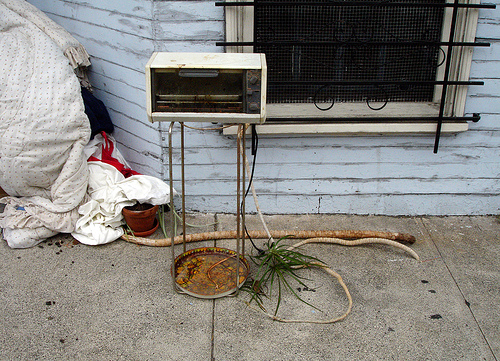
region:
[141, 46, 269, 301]
toaster oven sitting on a plant stand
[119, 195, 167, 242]
small pot for a plant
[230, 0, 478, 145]
window covered with black security bars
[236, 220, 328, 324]
house plant laying on a sidewalk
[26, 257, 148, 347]
sidewalk made of concrete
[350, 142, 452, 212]
light blue clapboard siding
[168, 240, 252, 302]
rusted area of a plant stand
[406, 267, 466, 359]
black stains on a sidewalk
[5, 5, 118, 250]
pile of clothing on a sidewalk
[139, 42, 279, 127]
white toaster oven outside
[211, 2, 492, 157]
Window has black wrought iron on it.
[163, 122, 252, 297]
Metal stand is sitting on sidewalk.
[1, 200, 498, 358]
Sidewalk is paved cement.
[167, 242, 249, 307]
A rusty tray is under the stand.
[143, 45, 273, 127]
A toaster oven is sitting on the stand.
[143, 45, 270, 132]
The toaster oven is white.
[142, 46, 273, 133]
Toaster oven shows signs of great use.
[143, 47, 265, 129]
The toaster oven appears quite dirty.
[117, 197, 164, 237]
Flower pot on ground beside stand.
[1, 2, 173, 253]
Pile of clothes lie against the house.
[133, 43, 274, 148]
the old toaster oven is white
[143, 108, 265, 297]
the stand is rusty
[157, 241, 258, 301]
the plate is rusty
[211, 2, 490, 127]
the window has iron bars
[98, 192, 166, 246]
the flower pot is red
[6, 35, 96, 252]
the big rag is polka dot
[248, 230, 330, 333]
the plant is green and out of place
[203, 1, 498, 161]
the window bars are black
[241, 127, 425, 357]
the cord is very long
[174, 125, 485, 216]
the house is blue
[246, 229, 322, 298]
a small green plant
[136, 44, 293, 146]
a broken toaster oven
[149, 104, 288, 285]
a small metal stand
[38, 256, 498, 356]
a grey cement sidewalk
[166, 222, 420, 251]
a long piece of wood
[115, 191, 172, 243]
a planting pot and saucer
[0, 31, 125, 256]
an old white comforter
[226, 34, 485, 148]
metal bars on window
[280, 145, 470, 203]
pale blue building siding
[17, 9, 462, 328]
some old stuff on street curb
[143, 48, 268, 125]
a white toaster oven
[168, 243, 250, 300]
a pan on the ground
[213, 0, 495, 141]
a window covered in bars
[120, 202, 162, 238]
a planter on the ground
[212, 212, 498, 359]
a cement slab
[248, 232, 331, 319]
a green plant on the ground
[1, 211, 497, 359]
a gray cement sidewalk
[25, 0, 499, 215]
a white building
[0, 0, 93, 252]
a white blanket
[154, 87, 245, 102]
a gray sheet in the toaster oven